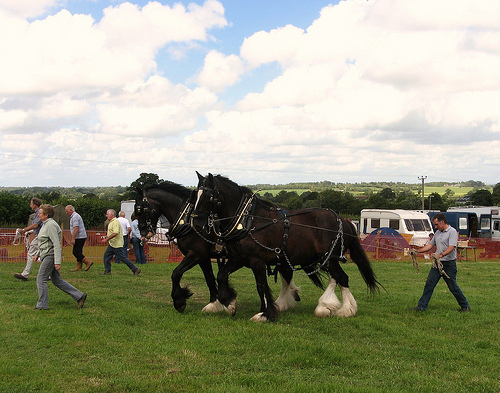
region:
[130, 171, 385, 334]
two horses on grass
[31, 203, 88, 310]
man in green shirt walking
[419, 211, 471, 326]
man holding reigns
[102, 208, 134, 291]
man in yellow shirt walking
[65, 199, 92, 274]
man in blue shirt walking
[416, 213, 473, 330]
man in dark pants holding reigns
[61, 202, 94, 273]
man in brown boots walking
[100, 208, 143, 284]
man in denim pant walking on grass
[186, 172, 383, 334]
horse walking on grass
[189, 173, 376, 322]
brown and white horse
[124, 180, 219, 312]
brown horse in grass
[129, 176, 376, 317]
two horses on grass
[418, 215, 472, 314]
man holding horse reins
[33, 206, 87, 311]
woman wearing grey shirt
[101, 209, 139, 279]
man wearing yellow shirt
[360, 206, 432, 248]
white trailor on grass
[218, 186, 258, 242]
black and gold reins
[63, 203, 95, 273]
man walking on grass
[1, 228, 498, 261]
orange plastic barrier fence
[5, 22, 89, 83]
white clouds in blue sky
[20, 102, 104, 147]
white clouds in blue sky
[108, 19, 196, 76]
white clouds in blue sky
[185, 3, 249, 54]
white clouds in blue sky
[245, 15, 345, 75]
white clouds in blue sky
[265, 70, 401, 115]
white clouds in blue sky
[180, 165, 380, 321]
large brown and white horse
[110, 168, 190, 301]
large brown and white horse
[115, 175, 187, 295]
brown and white horse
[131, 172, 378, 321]
horse running on the grass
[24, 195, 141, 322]
lot of people running in the lawn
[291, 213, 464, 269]
a person holding rope of the horse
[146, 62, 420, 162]
sky with clouds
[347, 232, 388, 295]
tail of the horse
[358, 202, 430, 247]
white color car parked in the parking area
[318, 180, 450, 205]
trees and electric post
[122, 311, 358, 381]
green grass in the lawn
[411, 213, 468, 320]
a man holding rope on his hand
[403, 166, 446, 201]
electric line with post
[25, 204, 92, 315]
man walking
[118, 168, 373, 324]
two horses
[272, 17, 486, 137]
clouds in the sky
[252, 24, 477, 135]
clouds are white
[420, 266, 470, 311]
man wearing pants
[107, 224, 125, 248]
yelllow shirt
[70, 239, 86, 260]
man wearing pants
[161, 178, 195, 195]
horse has black hair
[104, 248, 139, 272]
man is wearing blue jeans